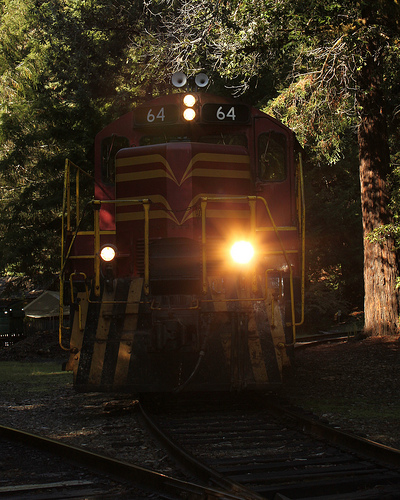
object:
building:
[0, 289, 71, 348]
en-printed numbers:
[133, 102, 252, 127]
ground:
[0, 333, 400, 499]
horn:
[171, 72, 186, 87]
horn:
[195, 73, 208, 88]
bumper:
[59, 277, 304, 392]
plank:
[249, 469, 400, 493]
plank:
[226, 460, 376, 483]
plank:
[212, 453, 359, 476]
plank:
[201, 449, 335, 468]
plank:
[178, 437, 330, 447]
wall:
[199, 150, 248, 188]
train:
[51, 71, 306, 393]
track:
[0, 398, 399, 499]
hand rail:
[59, 152, 306, 352]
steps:
[61, 199, 97, 280]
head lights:
[98, 243, 120, 264]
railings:
[1, 380, 398, 498]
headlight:
[231, 239, 256, 264]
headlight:
[183, 94, 196, 107]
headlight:
[183, 108, 196, 122]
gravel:
[2, 377, 224, 494]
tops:
[94, 90, 310, 161]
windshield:
[258, 133, 288, 182]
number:
[147, 108, 166, 123]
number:
[216, 106, 236, 122]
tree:
[0, 0, 400, 339]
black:
[200, 101, 251, 124]